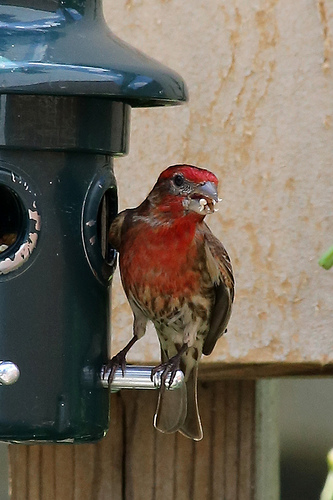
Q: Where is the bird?
A: At the bird house.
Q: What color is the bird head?
A: Red.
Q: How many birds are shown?
A: One.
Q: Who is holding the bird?
A: No one.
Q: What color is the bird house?
A: Blue.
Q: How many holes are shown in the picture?
A: Two.